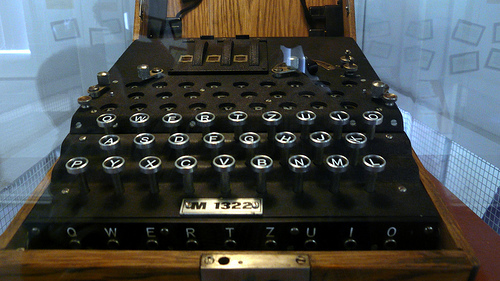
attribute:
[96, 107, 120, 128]
key — round, q, typewriter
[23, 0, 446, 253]
machine — black, teletype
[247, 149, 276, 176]
key — rounded, silver, black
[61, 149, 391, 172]
keys — several, round, metal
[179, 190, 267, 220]
plate — one, black, silver, metal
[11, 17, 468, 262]
box — brown, wooden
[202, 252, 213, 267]
screw — one, round, metal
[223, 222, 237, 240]
t — ONE, WHITE, CAPITAL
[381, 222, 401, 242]
o — CAPITAL, LETTER, WHITE, ONE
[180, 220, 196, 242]
r — ONE, WHITE, CAPITAL, LETTER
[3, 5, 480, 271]
machine — FAX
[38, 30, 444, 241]
machine — FAX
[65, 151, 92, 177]
p — LETTER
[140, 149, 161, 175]
x — LETTER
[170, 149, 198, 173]
c — LETTER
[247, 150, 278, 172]
b — LETTER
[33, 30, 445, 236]
typewriter — BLACK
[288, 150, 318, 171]
n — LETTER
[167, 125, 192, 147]
d — LETTER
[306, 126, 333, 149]
j — LETTER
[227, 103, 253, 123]
t — LETTER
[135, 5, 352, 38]
cabinet — LIGHT BROWN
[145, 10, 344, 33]
stripes — DARK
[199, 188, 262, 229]
plate — metal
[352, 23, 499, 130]
boxes — blue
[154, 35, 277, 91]
squares — yellow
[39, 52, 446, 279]
frame — wooden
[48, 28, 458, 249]
typewriter — antique